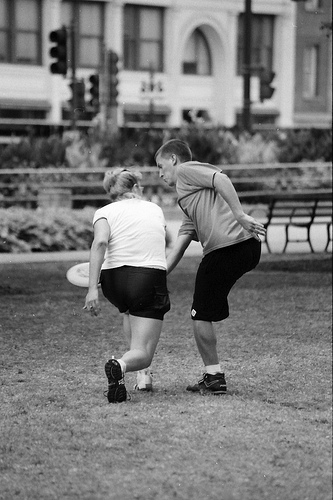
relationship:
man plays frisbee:
[152, 138, 271, 393] [69, 258, 98, 287]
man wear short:
[152, 138, 271, 393] [101, 269, 172, 318]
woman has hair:
[87, 163, 173, 404] [100, 166, 145, 200]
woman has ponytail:
[87, 163, 173, 404] [104, 162, 127, 188]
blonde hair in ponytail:
[103, 167, 143, 196] [104, 162, 127, 188]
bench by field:
[259, 194, 332, 250] [4, 257, 326, 499]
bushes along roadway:
[4, 130, 329, 177] [6, 118, 325, 164]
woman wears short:
[87, 163, 173, 404] [101, 269, 172, 318]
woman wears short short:
[87, 163, 173, 404] [101, 269, 172, 318]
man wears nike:
[152, 138, 271, 393] [200, 380, 221, 388]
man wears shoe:
[152, 138, 271, 393] [184, 375, 233, 397]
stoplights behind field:
[50, 26, 279, 110] [4, 257, 326, 499]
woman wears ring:
[87, 163, 173, 404] [89, 305, 96, 310]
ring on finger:
[89, 305, 96, 310] [90, 303, 95, 316]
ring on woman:
[89, 305, 96, 310] [87, 163, 173, 404]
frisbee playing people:
[69, 258, 98, 287] [84, 135, 266, 401]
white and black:
[93, 202, 169, 269] [192, 238, 262, 327]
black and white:
[192, 238, 262, 327] [93, 202, 169, 269]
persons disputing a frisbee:
[84, 135, 266, 401] [69, 258, 98, 287]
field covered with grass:
[4, 257, 326, 499] [6, 260, 327, 492]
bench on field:
[259, 194, 332, 250] [4, 257, 326, 499]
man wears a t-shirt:
[152, 138, 271, 393] [178, 164, 255, 252]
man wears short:
[152, 138, 271, 393] [101, 269, 172, 318]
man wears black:
[152, 138, 271, 393] [192, 238, 262, 327]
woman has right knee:
[87, 163, 173, 404] [130, 340, 157, 366]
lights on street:
[50, 26, 279, 110] [4, 121, 320, 138]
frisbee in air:
[69, 258, 98, 287] [56, 251, 102, 302]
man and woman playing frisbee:
[152, 138, 271, 393] [69, 258, 98, 287]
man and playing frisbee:
[152, 138, 271, 393] [69, 258, 98, 287]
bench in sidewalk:
[259, 194, 332, 250] [174, 221, 332, 250]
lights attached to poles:
[50, 26, 279, 110] [67, 2, 256, 128]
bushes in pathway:
[2, 206, 101, 252] [174, 221, 332, 250]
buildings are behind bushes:
[7, 5, 328, 124] [4, 130, 329, 177]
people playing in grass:
[84, 135, 266, 401] [6, 260, 327, 492]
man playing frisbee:
[152, 138, 271, 393] [69, 258, 98, 287]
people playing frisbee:
[84, 135, 266, 401] [69, 258, 98, 287]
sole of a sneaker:
[106, 360, 126, 401] [104, 356, 129, 404]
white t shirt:
[93, 202, 169, 269] [93, 198, 168, 269]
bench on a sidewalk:
[259, 194, 332, 250] [174, 221, 332, 250]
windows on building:
[2, 1, 283, 76] [5, 6, 293, 120]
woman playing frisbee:
[87, 163, 173, 404] [69, 258, 98, 287]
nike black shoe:
[200, 380, 221, 388] [184, 375, 233, 391]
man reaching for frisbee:
[152, 138, 271, 393] [69, 258, 98, 287]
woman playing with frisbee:
[87, 163, 173, 404] [69, 258, 98, 287]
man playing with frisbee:
[152, 138, 271, 393] [69, 258, 98, 287]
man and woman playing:
[152, 138, 271, 393] [67, 136, 264, 409]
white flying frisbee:
[67, 262, 98, 288] [69, 258, 98, 287]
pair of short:
[96, 269, 169, 319] [101, 269, 172, 318]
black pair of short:
[192, 238, 262, 327] [101, 269, 172, 318]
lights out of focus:
[50, 26, 279, 110] [43, 21, 282, 115]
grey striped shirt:
[176, 160, 252, 257] [178, 164, 255, 252]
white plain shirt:
[93, 202, 169, 269] [93, 198, 168, 269]